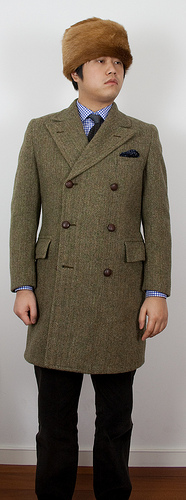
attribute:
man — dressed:
[17, 17, 169, 496]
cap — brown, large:
[63, 17, 130, 59]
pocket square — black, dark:
[119, 148, 141, 160]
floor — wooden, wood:
[145, 472, 185, 493]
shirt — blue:
[80, 108, 90, 123]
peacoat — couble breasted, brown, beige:
[33, 114, 160, 372]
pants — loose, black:
[28, 372, 130, 493]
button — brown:
[104, 265, 114, 281]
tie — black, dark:
[90, 112, 100, 130]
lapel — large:
[54, 117, 83, 164]